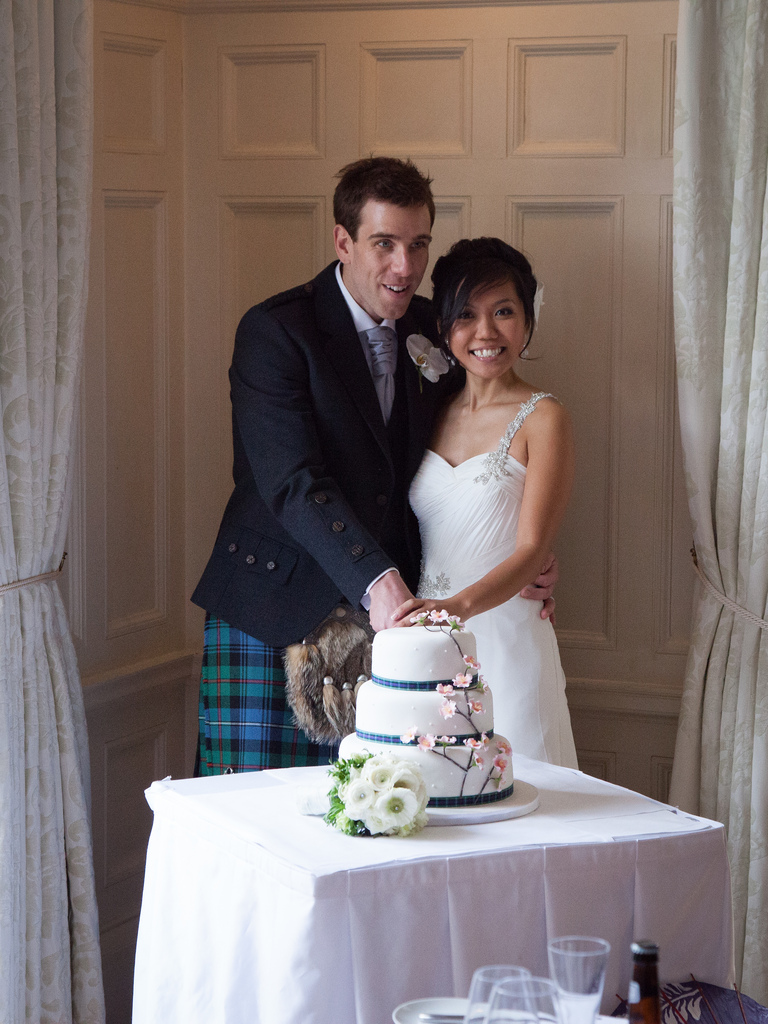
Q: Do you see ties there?
A: Yes, there is a tie.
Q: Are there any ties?
A: Yes, there is a tie.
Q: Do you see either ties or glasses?
A: Yes, there is a tie.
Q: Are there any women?
A: Yes, there is a woman.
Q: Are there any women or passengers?
A: Yes, there is a woman.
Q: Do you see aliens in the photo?
A: No, there are no aliens.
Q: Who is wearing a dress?
A: The woman is wearing a dress.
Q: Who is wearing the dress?
A: The woman is wearing a dress.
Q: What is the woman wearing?
A: The woman is wearing a dress.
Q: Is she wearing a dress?
A: Yes, the woman is wearing a dress.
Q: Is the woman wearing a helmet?
A: No, the woman is wearing a dress.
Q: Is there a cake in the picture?
A: Yes, there is a cake.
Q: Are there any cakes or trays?
A: Yes, there is a cake.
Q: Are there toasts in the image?
A: No, there are no toasts.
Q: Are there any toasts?
A: No, there are no toasts.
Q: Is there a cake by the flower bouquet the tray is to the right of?
A: Yes, there is a cake by the flower bouquet.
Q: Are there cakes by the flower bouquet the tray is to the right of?
A: Yes, there is a cake by the flower bouquet.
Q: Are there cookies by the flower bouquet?
A: No, there is a cake by the flower bouquet.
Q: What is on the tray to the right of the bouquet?
A: The cake is on the tray.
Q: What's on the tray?
A: The cake is on the tray.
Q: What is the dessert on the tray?
A: The dessert is a cake.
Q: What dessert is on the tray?
A: The dessert is a cake.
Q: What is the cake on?
A: The cake is on the tray.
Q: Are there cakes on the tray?
A: Yes, there is a cake on the tray.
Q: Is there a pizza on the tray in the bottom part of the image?
A: No, there is a cake on the tray.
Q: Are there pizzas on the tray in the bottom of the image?
A: No, there is a cake on the tray.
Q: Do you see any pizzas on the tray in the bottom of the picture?
A: No, there is a cake on the tray.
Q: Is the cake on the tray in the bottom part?
A: Yes, the cake is on the tray.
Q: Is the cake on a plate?
A: No, the cake is on the tray.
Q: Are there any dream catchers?
A: No, there are no dream catchers.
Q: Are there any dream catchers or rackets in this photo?
A: No, there are no dream catchers or rackets.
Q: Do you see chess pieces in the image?
A: No, there are no chess pieces.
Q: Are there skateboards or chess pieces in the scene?
A: No, there are no chess pieces or skateboards.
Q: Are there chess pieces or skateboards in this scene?
A: No, there are no chess pieces or skateboards.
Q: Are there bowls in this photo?
A: No, there are no bowls.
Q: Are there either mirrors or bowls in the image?
A: No, there are no bowls or mirrors.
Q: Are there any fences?
A: No, there are no fences.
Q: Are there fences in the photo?
A: No, there are no fences.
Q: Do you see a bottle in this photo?
A: Yes, there is a bottle.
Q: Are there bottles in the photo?
A: Yes, there is a bottle.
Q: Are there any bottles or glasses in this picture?
A: Yes, there is a bottle.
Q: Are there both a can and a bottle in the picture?
A: No, there is a bottle but no cans.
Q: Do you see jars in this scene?
A: No, there are no jars.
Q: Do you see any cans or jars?
A: No, there are no jars or cans.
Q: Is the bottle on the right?
A: Yes, the bottle is on the right of the image.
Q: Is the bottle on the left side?
A: No, the bottle is on the right of the image.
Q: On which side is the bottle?
A: The bottle is on the right of the image.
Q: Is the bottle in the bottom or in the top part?
A: The bottle is in the bottom of the image.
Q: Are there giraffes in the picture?
A: No, there are no giraffes.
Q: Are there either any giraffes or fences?
A: No, there are no giraffes or fences.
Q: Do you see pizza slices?
A: No, there are no pizza slices.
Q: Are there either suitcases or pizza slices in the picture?
A: No, there are no pizza slices or suitcases.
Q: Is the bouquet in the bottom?
A: Yes, the bouquet is in the bottom of the image.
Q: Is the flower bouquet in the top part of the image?
A: No, the flower bouquet is in the bottom of the image.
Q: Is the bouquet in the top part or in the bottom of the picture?
A: The bouquet is in the bottom of the image.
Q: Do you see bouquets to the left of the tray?
A: Yes, there is a bouquet to the left of the tray.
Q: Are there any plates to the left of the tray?
A: No, there is a bouquet to the left of the tray.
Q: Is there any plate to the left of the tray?
A: No, there is a bouquet to the left of the tray.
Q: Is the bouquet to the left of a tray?
A: Yes, the bouquet is to the left of a tray.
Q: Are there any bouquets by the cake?
A: Yes, there is a bouquet by the cake.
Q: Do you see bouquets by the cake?
A: Yes, there is a bouquet by the cake.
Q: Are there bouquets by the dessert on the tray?
A: Yes, there is a bouquet by the cake.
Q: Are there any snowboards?
A: No, there are no snowboards.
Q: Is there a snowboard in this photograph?
A: No, there are no snowboards.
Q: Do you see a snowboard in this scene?
A: No, there are no snowboards.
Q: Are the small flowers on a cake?
A: Yes, the flowers are on a cake.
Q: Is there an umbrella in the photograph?
A: No, there are no umbrellas.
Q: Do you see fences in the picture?
A: No, there are no fences.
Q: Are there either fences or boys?
A: No, there are no fences or boys.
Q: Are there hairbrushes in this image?
A: No, there are no hairbrushes.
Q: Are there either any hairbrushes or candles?
A: No, there are no hairbrushes or candles.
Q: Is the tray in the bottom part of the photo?
A: Yes, the tray is in the bottom of the image.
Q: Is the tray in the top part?
A: No, the tray is in the bottom of the image.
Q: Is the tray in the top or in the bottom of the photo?
A: The tray is in the bottom of the image.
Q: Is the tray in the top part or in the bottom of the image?
A: The tray is in the bottom of the image.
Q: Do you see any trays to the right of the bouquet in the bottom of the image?
A: Yes, there is a tray to the right of the bouquet.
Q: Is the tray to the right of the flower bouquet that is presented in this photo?
A: Yes, the tray is to the right of the flower bouquet.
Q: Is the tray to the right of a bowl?
A: No, the tray is to the right of the flower bouquet.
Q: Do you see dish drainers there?
A: No, there are no dish drainers.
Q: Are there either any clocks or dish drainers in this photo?
A: No, there are no dish drainers or clocks.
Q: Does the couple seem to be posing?
A: Yes, the couple is posing.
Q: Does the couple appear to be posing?
A: Yes, the couple is posing.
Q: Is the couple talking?
A: No, the couple is posing.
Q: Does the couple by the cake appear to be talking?
A: No, the couple is posing.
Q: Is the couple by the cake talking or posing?
A: The couple is posing.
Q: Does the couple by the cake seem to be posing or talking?
A: The couple is posing.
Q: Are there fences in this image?
A: No, there are no fences.